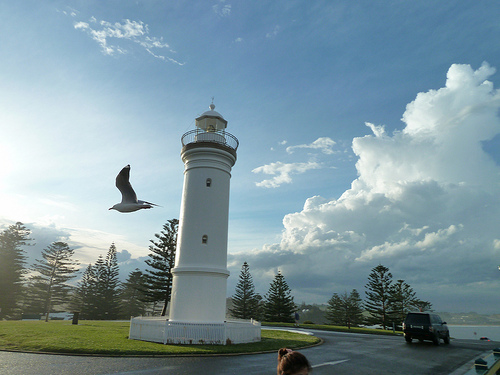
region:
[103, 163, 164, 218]
a bird in flight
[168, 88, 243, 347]
a white lighthouse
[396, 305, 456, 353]
a vehicle parked by the water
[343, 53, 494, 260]
clouds in the sky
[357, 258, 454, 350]
trees and a vehicle by the water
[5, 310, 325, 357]
grass at the base of a lighthouse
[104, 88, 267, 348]
a bird flying by a lighthouse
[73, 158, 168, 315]
a bird flying near the trees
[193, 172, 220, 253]
2 windows on a lighthouse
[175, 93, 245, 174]
the top section of a lighthouse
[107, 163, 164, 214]
seagull flying in air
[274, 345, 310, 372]
top of persons head with brown hair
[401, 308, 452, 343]
black SUV parked in parking lot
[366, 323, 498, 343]
blue body of water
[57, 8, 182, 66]
white clouds in the sky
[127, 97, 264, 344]
tall white lighthouse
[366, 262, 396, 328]
tall green tree in front of water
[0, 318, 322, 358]
large circle of green grass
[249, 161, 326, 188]
white cloud in the blue sky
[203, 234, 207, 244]
window on white light house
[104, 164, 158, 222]
Large bird flying in air.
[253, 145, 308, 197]
White cloud in sky.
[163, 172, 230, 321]
White building in grassy area.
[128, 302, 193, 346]
White fence around building.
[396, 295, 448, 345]
Car on dark pavement.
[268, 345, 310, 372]
Person has brown hair.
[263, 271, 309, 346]
Large tree in distance.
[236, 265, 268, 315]
Large tree in distance.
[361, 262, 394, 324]
Large tree in distance.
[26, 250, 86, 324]
Large tree in distance.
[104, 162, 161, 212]
The white flying bird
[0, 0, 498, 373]
A bright day within a lake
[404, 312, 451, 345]
The dark parked car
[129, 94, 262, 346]
The central white monument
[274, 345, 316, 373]
The partially seen human head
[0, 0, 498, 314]
A blue clouded sky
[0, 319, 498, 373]
The round about next to the monument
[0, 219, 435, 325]
The vegetated tree background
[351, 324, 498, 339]
The gray lake on the right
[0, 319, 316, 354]
The rounded green space